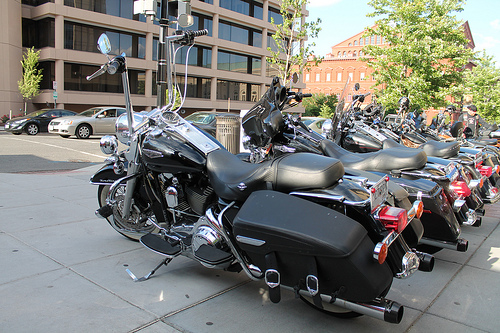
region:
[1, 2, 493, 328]
Exterior shot, daytime, city view, probably taken before late fall, or winter.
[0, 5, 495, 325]
Mostly man-made landscape with some natural elements.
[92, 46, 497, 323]
Row of parked motorcycles.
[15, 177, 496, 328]
Large, square tiles, on parking surface.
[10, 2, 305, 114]
Tan, highrise, office building, with rows of horizontal windows.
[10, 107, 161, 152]
Parking area, with cars.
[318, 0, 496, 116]
Red, brick building in the distance.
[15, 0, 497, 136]
Numerous, young-looking trees, with leaves.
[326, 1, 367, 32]
Pale, blue sky with clouds.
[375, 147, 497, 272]
Red tail lights, on motorcycles.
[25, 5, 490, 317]
motorcycles on a city street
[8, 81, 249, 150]
traffic on the street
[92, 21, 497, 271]
motorcycles parked along the sidewalk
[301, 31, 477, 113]
a brick red building in the background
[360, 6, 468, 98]
a tree above the motorcycle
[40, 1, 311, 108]
a brown building on the otherside of the street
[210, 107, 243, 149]
a trash can in the area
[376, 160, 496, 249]
break lights on the motorcycle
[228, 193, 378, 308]
a carrying compartment on the bike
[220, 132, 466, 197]
black seats on the motorcycle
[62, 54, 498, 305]
there are several motorcycles parked in this area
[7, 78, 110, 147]
two cars are across the street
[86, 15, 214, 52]
these are the bikes rear view mirrors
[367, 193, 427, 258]
these are the bikes tail lights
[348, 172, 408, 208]
this is the bikes license plate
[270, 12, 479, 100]
there are trees in the background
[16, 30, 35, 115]
a small tree next to the building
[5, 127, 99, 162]
this is a portion of the road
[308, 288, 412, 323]
this is the bikes exhaust pipe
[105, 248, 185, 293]
this is the bikes kick stand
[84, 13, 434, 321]
a black parked motorcycle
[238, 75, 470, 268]
a parked silver motorcycle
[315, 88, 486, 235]
a parked silver motorcycle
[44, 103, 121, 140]
a silver car in street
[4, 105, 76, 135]
a dark green car in street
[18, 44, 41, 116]
a small green tree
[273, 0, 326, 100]
a small green tree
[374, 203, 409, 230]
a motorcycle brake light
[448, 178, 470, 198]
a motorcycle brake light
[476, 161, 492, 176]
a motorcycle brake light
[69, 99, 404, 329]
this is a motorcycle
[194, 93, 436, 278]
this is a motorcycle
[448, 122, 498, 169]
this is a motorcycle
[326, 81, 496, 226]
this is a motorcycle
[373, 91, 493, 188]
this is a motorcycle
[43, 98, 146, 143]
this is a car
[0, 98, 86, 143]
this is a car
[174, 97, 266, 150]
this is a car